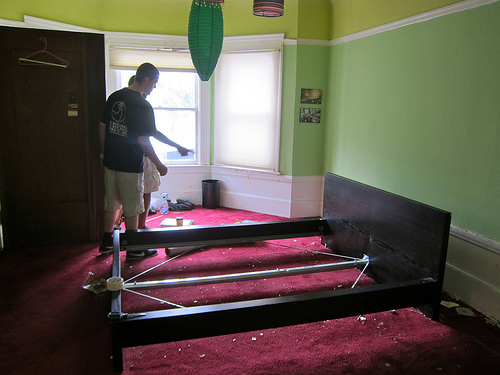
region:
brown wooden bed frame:
[99, 169, 453, 374]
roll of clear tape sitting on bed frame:
[105, 276, 124, 291]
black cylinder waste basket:
[200, 178, 220, 209]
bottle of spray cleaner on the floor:
[156, 193, 168, 215]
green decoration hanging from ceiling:
[187, 0, 224, 81]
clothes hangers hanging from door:
[17, 35, 70, 68]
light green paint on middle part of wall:
[277, 0, 497, 246]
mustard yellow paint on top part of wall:
[0, 0, 467, 40]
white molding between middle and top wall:
[282, 0, 498, 45]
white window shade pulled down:
[209, 47, 282, 174]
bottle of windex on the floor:
[156, 195, 173, 218]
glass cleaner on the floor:
[152, 188, 172, 218]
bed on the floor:
[91, 167, 459, 374]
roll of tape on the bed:
[98, 272, 130, 299]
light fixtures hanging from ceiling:
[180, 0, 295, 85]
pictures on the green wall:
[293, 78, 328, 133]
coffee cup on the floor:
[173, 210, 183, 232]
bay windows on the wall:
[13, 15, 290, 174]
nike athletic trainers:
[98, 226, 163, 265]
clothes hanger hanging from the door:
[10, 23, 73, 83]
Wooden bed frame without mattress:
[111, 153, 454, 367]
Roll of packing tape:
[103, 268, 130, 295]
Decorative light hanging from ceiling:
[174, 0, 232, 87]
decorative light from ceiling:
[250, 0, 302, 20]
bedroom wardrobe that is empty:
[6, 22, 109, 251]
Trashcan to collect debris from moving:
[197, 171, 232, 213]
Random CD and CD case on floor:
[451, 298, 473, 328]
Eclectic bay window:
[7, 13, 301, 202]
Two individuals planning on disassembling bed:
[94, 47, 201, 266]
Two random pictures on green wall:
[298, 65, 324, 140]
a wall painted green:
[330, 43, 493, 169]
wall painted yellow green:
[64, 3, 179, 25]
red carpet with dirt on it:
[356, 310, 428, 349]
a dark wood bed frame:
[106, 176, 453, 314]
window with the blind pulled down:
[212, 47, 285, 177]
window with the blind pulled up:
[112, 45, 203, 164]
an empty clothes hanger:
[14, 28, 74, 75]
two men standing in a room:
[102, 62, 192, 267]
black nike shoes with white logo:
[95, 239, 162, 266]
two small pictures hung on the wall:
[293, 80, 325, 132]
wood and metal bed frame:
[68, 160, 473, 370]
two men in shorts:
[80, 48, 228, 263]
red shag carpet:
[0, 161, 460, 372]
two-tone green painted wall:
[291, 1, 498, 218]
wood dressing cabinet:
[0, 5, 132, 315]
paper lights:
[180, 1, 317, 103]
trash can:
[185, 170, 236, 211]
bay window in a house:
[2, 6, 308, 207]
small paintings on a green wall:
[295, 84, 327, 131]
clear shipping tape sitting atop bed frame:
[103, 274, 130, 291]